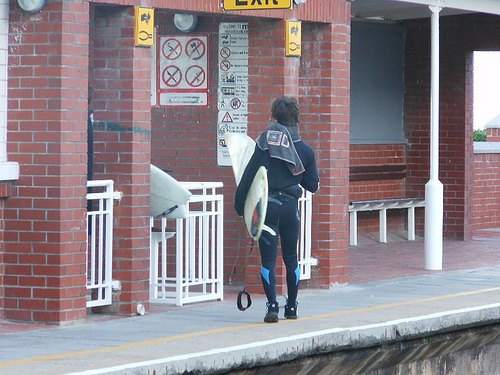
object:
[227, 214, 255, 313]
cord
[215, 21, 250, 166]
sign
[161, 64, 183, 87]
sign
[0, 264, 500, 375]
platform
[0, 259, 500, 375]
ground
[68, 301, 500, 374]
line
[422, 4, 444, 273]
pillar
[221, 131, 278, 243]
surfboard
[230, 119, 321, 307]
wet suit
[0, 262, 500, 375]
pavement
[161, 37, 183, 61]
sign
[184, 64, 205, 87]
sign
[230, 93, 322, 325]
surfer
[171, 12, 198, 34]
light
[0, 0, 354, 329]
wall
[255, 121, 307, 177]
towel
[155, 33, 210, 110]
placard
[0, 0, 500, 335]
building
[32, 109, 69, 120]
bricks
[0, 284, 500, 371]
line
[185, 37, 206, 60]
sign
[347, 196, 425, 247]
bench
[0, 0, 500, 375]
transportation station